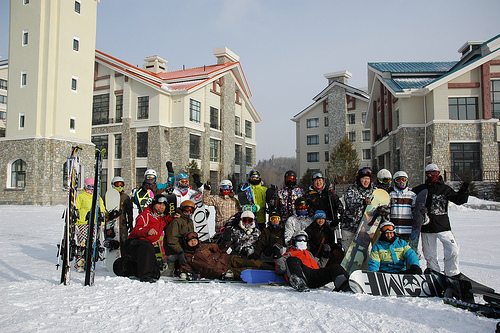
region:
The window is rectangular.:
[133, 91, 150, 121]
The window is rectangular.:
[303, 113, 322, 132]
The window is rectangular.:
[301, 132, 323, 147]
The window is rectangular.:
[301, 148, 322, 164]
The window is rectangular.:
[206, 100, 223, 132]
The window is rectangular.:
[241, 118, 253, 141]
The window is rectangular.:
[444, 90, 484, 122]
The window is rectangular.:
[205, 133, 225, 164]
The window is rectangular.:
[241, 143, 255, 169]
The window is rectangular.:
[110, 128, 128, 163]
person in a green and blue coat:
[364, 215, 422, 285]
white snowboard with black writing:
[342, 260, 457, 303]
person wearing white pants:
[410, 160, 481, 277]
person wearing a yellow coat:
[61, 170, 109, 273]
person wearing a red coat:
[126, 191, 184, 277]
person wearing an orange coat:
[277, 223, 349, 297]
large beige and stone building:
[1, 35, 268, 213]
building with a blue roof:
[285, 19, 498, 225]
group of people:
[30, 137, 471, 305]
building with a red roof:
[0, 37, 272, 223]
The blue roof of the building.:
[375, 32, 497, 79]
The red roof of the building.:
[95, 36, 262, 106]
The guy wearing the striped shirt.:
[378, 188, 419, 240]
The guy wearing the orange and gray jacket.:
[274, 250, 341, 275]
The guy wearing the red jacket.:
[136, 210, 166, 240]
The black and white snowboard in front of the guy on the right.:
[352, 273, 452, 295]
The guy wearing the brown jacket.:
[182, 245, 231, 274]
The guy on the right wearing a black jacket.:
[410, 176, 456, 231]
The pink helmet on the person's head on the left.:
[85, 180, 94, 190]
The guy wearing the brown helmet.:
[170, 195, 195, 250]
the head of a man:
[141, 192, 176, 218]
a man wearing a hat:
[123, 186, 185, 222]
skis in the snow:
[38, 81, 135, 295]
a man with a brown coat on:
[175, 223, 244, 287]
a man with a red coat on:
[128, 181, 194, 246]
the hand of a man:
[144, 215, 173, 245]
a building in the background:
[58, 40, 306, 217]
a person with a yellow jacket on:
[63, 184, 127, 231]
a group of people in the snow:
[64, 148, 419, 311]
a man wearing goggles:
[377, 155, 424, 193]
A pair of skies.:
[60, 147, 102, 287]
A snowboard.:
[348, 269, 443, 296]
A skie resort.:
[5, 3, 257, 217]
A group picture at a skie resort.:
[60, 147, 474, 309]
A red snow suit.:
[131, 207, 173, 241]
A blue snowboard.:
[238, 267, 284, 287]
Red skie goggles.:
[283, 171, 297, 188]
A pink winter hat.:
[84, 176, 99, 196]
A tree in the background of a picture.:
[250, 146, 302, 256]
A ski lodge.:
[295, 39, 497, 205]